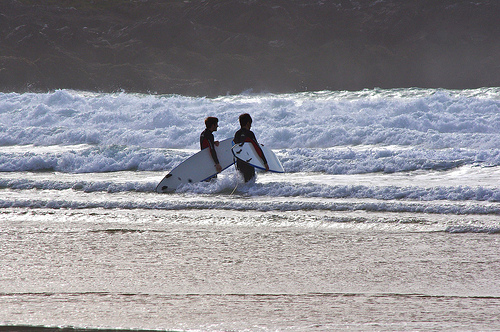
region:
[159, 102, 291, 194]
two men carrying white surfboards in the ocean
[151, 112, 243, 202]
man in red and black wet suit with white surf board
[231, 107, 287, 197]
man with dark hair in dark wet suit carrying white surfboard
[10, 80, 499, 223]
white foamy waves of ocean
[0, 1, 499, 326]
grey ocean water with white waves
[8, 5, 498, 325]
sunny clear outdoor surfing scene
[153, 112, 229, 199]
blond man walking into ocean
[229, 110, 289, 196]
dark haired man walking into ocean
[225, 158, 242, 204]
white cord dangling from surfboard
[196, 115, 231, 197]
profile of blond surfer man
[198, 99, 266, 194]
two people in the ocean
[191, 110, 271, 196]
two people going surfing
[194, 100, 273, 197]
two surfers carrying boards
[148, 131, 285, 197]
two white surfboards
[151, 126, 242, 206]
a surfboard with its end in the water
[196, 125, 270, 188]
two matching wetsuits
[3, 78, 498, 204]
white waves in the water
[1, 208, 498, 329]
calmer water near the shore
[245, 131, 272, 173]
right arm over a board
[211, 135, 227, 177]
two hands on a board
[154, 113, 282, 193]
two people and their surfboards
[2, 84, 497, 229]
waves breaking toward the shore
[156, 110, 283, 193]
young men carrying white surfboards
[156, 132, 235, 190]
surfboard with a tip in the water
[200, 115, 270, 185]
two men wearing wet suits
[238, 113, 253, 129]
the head of the man on the right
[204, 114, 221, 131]
head of the man on the left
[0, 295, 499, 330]
shallow water lapping the beach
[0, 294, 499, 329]
shallow water on the sand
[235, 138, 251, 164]
fins on the bottom of the surfboard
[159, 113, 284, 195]
Two surfers in the ocean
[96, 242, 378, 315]
Brown sandy water of the ocean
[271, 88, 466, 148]
White foamy waves in the ocean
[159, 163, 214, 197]
End of white surfboard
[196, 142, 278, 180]
Arms wrapped around boards for carrying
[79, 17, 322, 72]
Grey water of the ocean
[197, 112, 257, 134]
Heads of the two surfers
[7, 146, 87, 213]
Ripples of waves in the water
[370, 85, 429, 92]
Green tip of wave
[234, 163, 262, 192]
Legs of one surfer